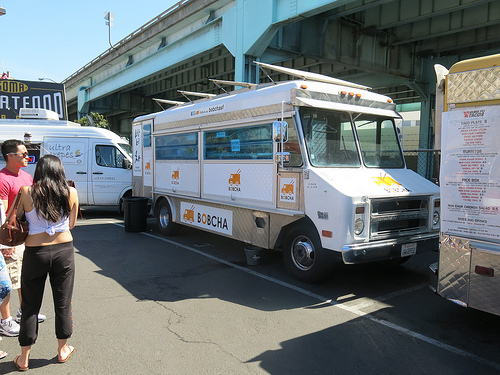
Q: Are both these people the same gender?
A: No, they are both male and female.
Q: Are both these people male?
A: No, they are both male and female.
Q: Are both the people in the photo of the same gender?
A: No, they are both male and female.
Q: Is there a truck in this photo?
A: Yes, there is a truck.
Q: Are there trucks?
A: Yes, there is a truck.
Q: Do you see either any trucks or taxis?
A: Yes, there is a truck.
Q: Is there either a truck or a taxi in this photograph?
A: Yes, there is a truck.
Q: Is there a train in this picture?
A: No, there are no trains.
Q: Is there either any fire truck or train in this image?
A: No, there are no trains or fire trucks.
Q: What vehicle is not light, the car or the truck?
A: The car is not light.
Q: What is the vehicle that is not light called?
A: The vehicle is a car.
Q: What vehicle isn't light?
A: The vehicle is a car.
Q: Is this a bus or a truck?
A: This is a truck.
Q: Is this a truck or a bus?
A: This is a truck.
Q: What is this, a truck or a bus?
A: This is a truck.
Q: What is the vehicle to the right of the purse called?
A: The vehicle is a truck.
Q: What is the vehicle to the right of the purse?
A: The vehicle is a truck.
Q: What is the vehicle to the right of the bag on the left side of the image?
A: The vehicle is a truck.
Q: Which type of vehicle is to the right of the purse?
A: The vehicle is a truck.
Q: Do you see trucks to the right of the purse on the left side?
A: Yes, there is a truck to the right of the purse.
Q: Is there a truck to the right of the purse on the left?
A: Yes, there is a truck to the right of the purse.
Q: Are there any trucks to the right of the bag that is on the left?
A: Yes, there is a truck to the right of the purse.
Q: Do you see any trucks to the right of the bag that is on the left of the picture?
A: Yes, there is a truck to the right of the purse.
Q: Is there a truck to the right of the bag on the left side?
A: Yes, there is a truck to the right of the purse.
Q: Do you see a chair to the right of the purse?
A: No, there is a truck to the right of the purse.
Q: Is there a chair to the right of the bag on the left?
A: No, there is a truck to the right of the purse.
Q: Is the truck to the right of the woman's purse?
A: Yes, the truck is to the right of the purse.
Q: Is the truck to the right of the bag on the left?
A: Yes, the truck is to the right of the purse.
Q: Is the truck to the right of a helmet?
A: No, the truck is to the right of the purse.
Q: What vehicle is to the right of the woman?
A: The vehicle is a truck.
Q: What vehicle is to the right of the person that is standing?
A: The vehicle is a truck.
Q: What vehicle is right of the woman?
A: The vehicle is a truck.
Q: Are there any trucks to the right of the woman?
A: Yes, there is a truck to the right of the woman.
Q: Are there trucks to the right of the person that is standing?
A: Yes, there is a truck to the right of the woman.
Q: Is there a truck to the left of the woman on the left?
A: No, the truck is to the right of the woman.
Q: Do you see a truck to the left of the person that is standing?
A: No, the truck is to the right of the woman.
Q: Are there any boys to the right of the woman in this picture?
A: No, there is a truck to the right of the woman.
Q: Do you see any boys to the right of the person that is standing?
A: No, there is a truck to the right of the woman.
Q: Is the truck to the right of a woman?
A: Yes, the truck is to the right of a woman.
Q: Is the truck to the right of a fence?
A: No, the truck is to the right of a woman.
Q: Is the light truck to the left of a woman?
A: No, the truck is to the right of a woman.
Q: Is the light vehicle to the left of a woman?
A: No, the truck is to the right of a woman.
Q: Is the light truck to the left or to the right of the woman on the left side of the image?
A: The truck is to the right of the woman.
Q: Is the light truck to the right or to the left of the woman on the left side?
A: The truck is to the right of the woman.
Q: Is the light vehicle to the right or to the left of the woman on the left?
A: The truck is to the right of the woman.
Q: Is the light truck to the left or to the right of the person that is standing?
A: The truck is to the right of the woman.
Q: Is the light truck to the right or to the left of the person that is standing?
A: The truck is to the right of the woman.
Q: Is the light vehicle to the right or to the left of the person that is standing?
A: The truck is to the right of the woman.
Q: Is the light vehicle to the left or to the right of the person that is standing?
A: The truck is to the right of the woman.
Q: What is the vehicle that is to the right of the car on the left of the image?
A: The vehicle is a truck.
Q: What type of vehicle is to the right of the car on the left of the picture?
A: The vehicle is a truck.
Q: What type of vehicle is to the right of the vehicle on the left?
A: The vehicle is a truck.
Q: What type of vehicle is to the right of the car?
A: The vehicle is a truck.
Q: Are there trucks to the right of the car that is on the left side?
A: Yes, there is a truck to the right of the car.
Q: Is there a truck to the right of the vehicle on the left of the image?
A: Yes, there is a truck to the right of the car.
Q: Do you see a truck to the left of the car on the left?
A: No, the truck is to the right of the car.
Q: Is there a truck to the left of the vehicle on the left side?
A: No, the truck is to the right of the car.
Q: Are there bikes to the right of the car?
A: No, there is a truck to the right of the car.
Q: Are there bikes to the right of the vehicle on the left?
A: No, there is a truck to the right of the car.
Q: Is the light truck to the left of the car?
A: No, the truck is to the right of the car.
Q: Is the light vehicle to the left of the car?
A: No, the truck is to the right of the car.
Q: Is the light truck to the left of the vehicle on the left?
A: No, the truck is to the right of the car.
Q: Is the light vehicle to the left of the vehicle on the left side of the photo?
A: No, the truck is to the right of the car.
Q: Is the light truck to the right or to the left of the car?
A: The truck is to the right of the car.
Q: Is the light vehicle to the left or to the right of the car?
A: The truck is to the right of the car.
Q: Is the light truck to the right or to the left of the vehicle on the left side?
A: The truck is to the right of the car.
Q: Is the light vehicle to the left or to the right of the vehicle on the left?
A: The truck is to the right of the car.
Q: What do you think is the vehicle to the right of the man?
A: The vehicle is a truck.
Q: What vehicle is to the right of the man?
A: The vehicle is a truck.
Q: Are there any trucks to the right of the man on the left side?
A: Yes, there is a truck to the right of the man.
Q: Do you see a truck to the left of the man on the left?
A: No, the truck is to the right of the man.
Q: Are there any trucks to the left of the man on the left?
A: No, the truck is to the right of the man.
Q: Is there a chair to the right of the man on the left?
A: No, there is a truck to the right of the man.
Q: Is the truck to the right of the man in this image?
A: Yes, the truck is to the right of the man.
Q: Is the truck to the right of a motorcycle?
A: No, the truck is to the right of the man.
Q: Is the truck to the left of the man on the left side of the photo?
A: No, the truck is to the right of the man.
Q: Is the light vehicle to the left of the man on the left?
A: No, the truck is to the right of the man.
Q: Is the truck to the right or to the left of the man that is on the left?
A: The truck is to the right of the man.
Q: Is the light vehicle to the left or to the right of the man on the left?
A: The truck is to the right of the man.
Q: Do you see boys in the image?
A: No, there are no boys.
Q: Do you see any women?
A: Yes, there is a woman.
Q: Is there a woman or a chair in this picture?
A: Yes, there is a woman.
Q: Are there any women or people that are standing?
A: Yes, the woman is standing.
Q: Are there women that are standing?
A: Yes, there is a woman that is standing.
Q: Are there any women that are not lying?
A: Yes, there is a woman that is standing.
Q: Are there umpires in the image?
A: No, there are no umpires.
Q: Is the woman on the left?
A: Yes, the woman is on the left of the image.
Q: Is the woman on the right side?
A: No, the woman is on the left of the image.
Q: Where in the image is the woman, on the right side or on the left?
A: The woman is on the left of the image.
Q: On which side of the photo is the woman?
A: The woman is on the left of the image.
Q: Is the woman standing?
A: Yes, the woman is standing.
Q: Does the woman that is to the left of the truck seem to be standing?
A: Yes, the woman is standing.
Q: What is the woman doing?
A: The woman is standing.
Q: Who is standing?
A: The woman is standing.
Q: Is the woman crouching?
A: No, the woman is standing.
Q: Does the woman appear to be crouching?
A: No, the woman is standing.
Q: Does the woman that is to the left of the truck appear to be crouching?
A: No, the woman is standing.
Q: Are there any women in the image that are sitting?
A: No, there is a woman but she is standing.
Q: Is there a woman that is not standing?
A: No, there is a woman but she is standing.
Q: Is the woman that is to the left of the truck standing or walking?
A: The woman is standing.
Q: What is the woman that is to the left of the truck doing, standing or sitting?
A: The woman is standing.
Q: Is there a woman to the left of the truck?
A: Yes, there is a woman to the left of the truck.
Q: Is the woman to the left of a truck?
A: Yes, the woman is to the left of a truck.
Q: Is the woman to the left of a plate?
A: No, the woman is to the left of a truck.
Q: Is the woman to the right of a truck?
A: No, the woman is to the left of a truck.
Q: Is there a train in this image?
A: No, there are no trains.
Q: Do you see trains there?
A: No, there are no trains.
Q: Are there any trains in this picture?
A: No, there are no trains.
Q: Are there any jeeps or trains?
A: No, there are no trains or jeeps.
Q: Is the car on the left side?
A: Yes, the car is on the left of the image.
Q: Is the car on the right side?
A: No, the car is on the left of the image.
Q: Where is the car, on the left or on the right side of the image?
A: The car is on the left of the image.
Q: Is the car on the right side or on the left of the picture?
A: The car is on the left of the image.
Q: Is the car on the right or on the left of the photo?
A: The car is on the left of the image.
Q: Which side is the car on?
A: The car is on the left of the image.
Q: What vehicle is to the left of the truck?
A: The vehicle is a car.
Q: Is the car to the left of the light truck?
A: Yes, the car is to the left of the truck.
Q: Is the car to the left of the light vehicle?
A: Yes, the car is to the left of the truck.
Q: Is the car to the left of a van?
A: No, the car is to the left of the truck.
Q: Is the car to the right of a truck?
A: No, the car is to the left of a truck.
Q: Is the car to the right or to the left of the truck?
A: The car is to the left of the truck.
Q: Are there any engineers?
A: No, there are no engineers.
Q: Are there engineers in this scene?
A: No, there are no engineers.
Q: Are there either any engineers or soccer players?
A: No, there are no engineers or soccer players.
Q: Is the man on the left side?
A: Yes, the man is on the left of the image.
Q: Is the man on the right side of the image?
A: No, the man is on the left of the image.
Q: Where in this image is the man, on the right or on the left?
A: The man is on the left of the image.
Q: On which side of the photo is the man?
A: The man is on the left of the image.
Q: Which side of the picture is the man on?
A: The man is on the left of the image.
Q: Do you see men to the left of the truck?
A: Yes, there is a man to the left of the truck.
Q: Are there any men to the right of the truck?
A: No, the man is to the left of the truck.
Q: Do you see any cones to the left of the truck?
A: No, there is a man to the left of the truck.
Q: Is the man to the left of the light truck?
A: Yes, the man is to the left of the truck.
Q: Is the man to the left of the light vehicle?
A: Yes, the man is to the left of the truck.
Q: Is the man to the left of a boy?
A: No, the man is to the left of the truck.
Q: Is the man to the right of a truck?
A: No, the man is to the left of a truck.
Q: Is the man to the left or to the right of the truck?
A: The man is to the left of the truck.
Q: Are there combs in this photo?
A: No, there are no combs.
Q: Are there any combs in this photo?
A: No, there are no combs.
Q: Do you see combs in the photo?
A: No, there are no combs.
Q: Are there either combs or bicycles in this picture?
A: No, there are no combs or bicycles.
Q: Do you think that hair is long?
A: Yes, the hair is long.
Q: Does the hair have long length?
A: Yes, the hair is long.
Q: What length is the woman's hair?
A: The hair is long.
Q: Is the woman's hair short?
A: No, the hair is long.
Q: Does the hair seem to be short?
A: No, the hair is long.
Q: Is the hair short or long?
A: The hair is long.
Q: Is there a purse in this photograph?
A: Yes, there is a purse.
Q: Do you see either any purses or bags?
A: Yes, there is a purse.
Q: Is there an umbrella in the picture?
A: No, there are no umbrellas.